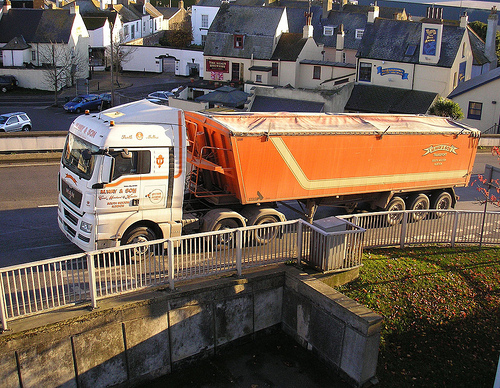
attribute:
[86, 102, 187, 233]
cab — white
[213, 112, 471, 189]
bed — orange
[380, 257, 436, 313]
grass — green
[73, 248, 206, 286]
gate — white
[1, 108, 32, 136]
car — silver, parked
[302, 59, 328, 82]
window — closed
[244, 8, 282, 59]
roof — grey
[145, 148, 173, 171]
design — orange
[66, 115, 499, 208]
truck — big, large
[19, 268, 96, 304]
fence — metal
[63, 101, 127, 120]
car — gray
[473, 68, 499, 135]
house — beige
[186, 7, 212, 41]
building — white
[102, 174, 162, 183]
stripe — orange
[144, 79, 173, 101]
car — blue, small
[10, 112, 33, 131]
suv — grey, small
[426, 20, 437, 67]
sign — blue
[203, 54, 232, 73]
sign — red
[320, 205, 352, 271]
can — grey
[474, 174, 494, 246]
tree — small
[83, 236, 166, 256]
rail — white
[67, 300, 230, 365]
wall — cement, grey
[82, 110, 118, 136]
lights — orange